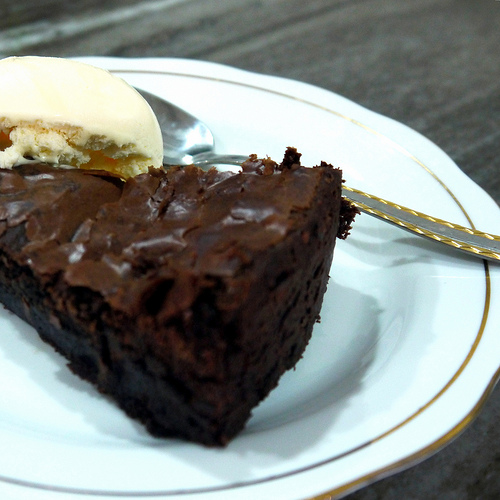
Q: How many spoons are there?
A: One.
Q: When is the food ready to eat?
A: Now.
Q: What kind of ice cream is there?
A: Vanilla.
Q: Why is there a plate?
A: To put the food on.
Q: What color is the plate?
A: White.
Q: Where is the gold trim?
A: Plate and spoon.